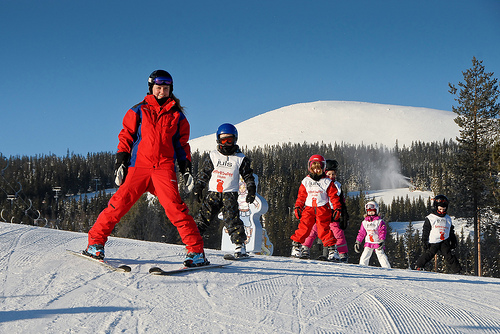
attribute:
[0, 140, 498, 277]
tree — green, around, tall, pine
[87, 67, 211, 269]
skier — female, young, adult, child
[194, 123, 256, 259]
child — modeling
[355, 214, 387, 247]
coat — white, pink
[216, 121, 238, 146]
helmet — blue, red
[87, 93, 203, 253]
suit — purple, black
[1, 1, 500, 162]
sky — blue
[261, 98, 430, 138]
mountain — snowy